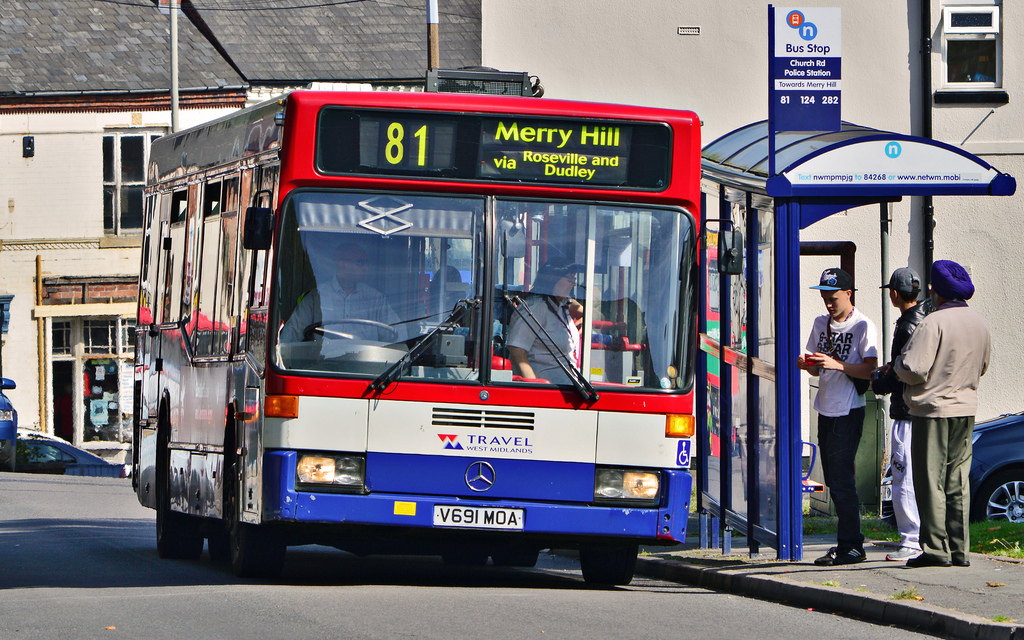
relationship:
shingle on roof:
[131, 63, 315, 111] [227, 27, 244, 46]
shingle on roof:
[43, 74, 299, 127] [335, 38, 352, 49]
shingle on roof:
[71, 24, 130, 117] [88, 48, 105, 65]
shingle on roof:
[250, 50, 447, 85] [375, 19, 398, 39]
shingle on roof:
[21, 13, 76, 78] [113, 39, 133, 53]